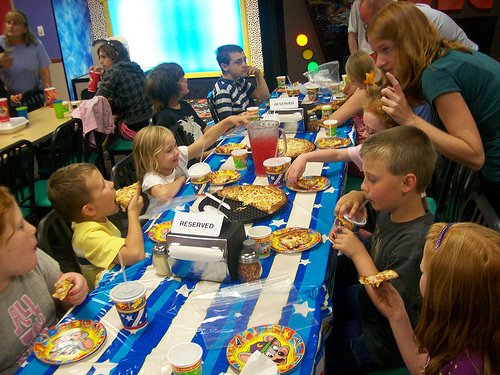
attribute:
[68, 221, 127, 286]
shirt — yellow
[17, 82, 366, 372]
tablecloth — dark, blue, aqua, white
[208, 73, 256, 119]
shirt — black, white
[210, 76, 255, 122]
shirt — white, black, striped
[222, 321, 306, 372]
plate — colorful, paper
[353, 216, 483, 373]
girl — red-haired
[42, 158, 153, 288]
boy — little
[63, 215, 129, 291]
shirt — yellow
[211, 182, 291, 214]
pizza — half eaten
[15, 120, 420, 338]
kids — eating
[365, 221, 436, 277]
shirt — blue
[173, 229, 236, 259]
dispenser — silver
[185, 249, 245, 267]
dispenser — silver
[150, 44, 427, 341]
people — seated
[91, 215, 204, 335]
stars — white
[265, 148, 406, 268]
boy — drinking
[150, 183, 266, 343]
sign — white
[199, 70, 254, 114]
shirt — striped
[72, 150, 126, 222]
boy — eating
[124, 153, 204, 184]
girl — smiling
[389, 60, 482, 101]
shirt — blue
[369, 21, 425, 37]
hair — red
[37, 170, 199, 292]
child — eating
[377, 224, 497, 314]
child — eating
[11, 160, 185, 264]
child — eating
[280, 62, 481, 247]
child — drinking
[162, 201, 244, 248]
sign — white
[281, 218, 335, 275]
plate — paper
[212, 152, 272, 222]
pizza — halved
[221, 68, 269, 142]
shirt — striped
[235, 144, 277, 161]
soda — red